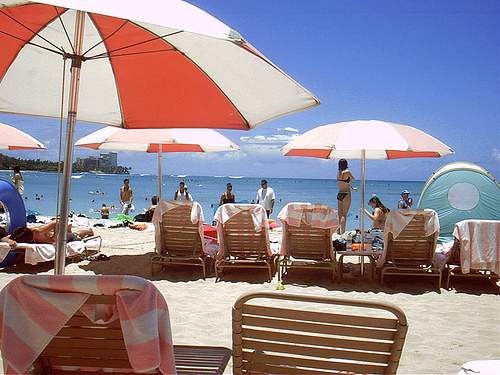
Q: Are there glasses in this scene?
A: No, there are no glasses.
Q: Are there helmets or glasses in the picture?
A: No, there are no glasses or helmets.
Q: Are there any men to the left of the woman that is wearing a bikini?
A: Yes, there is a man to the left of the woman.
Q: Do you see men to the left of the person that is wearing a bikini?
A: Yes, there is a man to the left of the woman.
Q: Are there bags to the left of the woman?
A: No, there is a man to the left of the woman.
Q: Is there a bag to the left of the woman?
A: No, there is a man to the left of the woman.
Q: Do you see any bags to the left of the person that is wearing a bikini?
A: No, there is a man to the left of the woman.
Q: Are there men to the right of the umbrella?
A: No, the man is to the left of the umbrella.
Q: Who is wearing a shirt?
A: The man is wearing a shirt.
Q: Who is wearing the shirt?
A: The man is wearing a shirt.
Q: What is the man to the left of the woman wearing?
A: The man is wearing a shirt.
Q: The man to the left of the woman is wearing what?
A: The man is wearing a shirt.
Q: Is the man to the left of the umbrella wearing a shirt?
A: Yes, the man is wearing a shirt.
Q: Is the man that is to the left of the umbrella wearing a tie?
A: No, the man is wearing a shirt.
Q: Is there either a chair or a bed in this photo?
A: Yes, there is a chair.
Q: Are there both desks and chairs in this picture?
A: No, there is a chair but no desks.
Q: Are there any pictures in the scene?
A: No, there are no pictures.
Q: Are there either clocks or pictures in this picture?
A: No, there are no pictures or clocks.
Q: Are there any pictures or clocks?
A: No, there are no pictures or clocks.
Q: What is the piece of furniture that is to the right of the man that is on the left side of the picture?
A: The piece of furniture is a chair.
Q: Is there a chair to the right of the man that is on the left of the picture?
A: Yes, there is a chair to the right of the man.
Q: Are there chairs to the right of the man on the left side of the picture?
A: Yes, there is a chair to the right of the man.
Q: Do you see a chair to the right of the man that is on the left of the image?
A: Yes, there is a chair to the right of the man.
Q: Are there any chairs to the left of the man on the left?
A: No, the chair is to the right of the man.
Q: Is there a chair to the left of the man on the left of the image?
A: No, the chair is to the right of the man.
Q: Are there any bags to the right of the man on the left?
A: No, there is a chair to the right of the man.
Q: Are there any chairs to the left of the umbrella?
A: Yes, there is a chair to the left of the umbrella.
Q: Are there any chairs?
A: Yes, there is a chair.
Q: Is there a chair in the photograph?
A: Yes, there is a chair.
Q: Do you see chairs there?
A: Yes, there is a chair.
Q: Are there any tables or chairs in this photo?
A: Yes, there is a chair.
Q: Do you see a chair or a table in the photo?
A: Yes, there is a chair.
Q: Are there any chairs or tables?
A: Yes, there is a chair.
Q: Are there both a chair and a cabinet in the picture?
A: No, there is a chair but no cabinets.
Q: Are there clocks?
A: No, there are no clocks.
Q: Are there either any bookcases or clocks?
A: No, there are no clocks or bookcases.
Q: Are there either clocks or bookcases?
A: No, there are no clocks or bookcases.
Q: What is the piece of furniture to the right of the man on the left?
A: The piece of furniture is a chair.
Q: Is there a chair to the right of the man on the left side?
A: Yes, there is a chair to the right of the man.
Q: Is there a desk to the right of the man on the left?
A: No, there is a chair to the right of the man.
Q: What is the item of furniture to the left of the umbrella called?
A: The piece of furniture is a chair.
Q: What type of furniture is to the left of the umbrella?
A: The piece of furniture is a chair.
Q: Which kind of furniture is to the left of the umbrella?
A: The piece of furniture is a chair.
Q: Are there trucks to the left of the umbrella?
A: No, there is a chair to the left of the umbrella.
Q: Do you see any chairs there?
A: Yes, there is a chair.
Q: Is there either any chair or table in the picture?
A: Yes, there is a chair.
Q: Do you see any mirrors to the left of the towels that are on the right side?
A: No, there is a chair to the left of the towels.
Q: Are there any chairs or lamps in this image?
A: Yes, there is a chair.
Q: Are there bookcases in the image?
A: No, there are no bookcases.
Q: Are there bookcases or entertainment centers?
A: No, there are no bookcases or entertainment centers.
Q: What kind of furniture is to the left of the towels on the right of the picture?
A: The piece of furniture is a chair.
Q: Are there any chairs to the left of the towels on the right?
A: Yes, there is a chair to the left of the towels.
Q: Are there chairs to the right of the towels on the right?
A: No, the chair is to the left of the towels.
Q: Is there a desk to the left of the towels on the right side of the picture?
A: No, there is a chair to the left of the towels.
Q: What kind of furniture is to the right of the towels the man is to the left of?
A: The piece of furniture is a chair.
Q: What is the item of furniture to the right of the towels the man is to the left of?
A: The piece of furniture is a chair.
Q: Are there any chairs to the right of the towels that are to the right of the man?
A: Yes, there is a chair to the right of the towels.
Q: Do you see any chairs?
A: Yes, there is a chair.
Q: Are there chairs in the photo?
A: Yes, there is a chair.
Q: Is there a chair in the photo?
A: Yes, there is a chair.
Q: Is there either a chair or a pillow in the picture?
A: Yes, there is a chair.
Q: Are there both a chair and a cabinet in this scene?
A: No, there is a chair but no cabinets.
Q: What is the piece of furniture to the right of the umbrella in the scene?
A: The piece of furniture is a chair.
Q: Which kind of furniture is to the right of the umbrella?
A: The piece of furniture is a chair.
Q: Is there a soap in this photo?
A: No, there are no soaps.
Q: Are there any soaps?
A: No, there are no soaps.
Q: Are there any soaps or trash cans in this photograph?
A: No, there are no soaps or trash cans.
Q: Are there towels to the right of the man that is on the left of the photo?
A: Yes, there are towels to the right of the man.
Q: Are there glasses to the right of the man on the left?
A: No, there are towels to the right of the man.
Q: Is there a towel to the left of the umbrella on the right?
A: Yes, there are towels to the left of the umbrella.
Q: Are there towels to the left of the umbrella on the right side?
A: Yes, there are towels to the left of the umbrella.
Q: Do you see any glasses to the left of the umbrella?
A: No, there are towels to the left of the umbrella.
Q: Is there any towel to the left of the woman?
A: Yes, there are towels to the left of the woman.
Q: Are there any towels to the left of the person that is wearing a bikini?
A: Yes, there are towels to the left of the woman.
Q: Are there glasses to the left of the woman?
A: No, there are towels to the left of the woman.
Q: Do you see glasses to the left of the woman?
A: No, there are towels to the left of the woman.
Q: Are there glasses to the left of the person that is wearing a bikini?
A: No, there are towels to the left of the woman.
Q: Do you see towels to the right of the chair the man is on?
A: Yes, there are towels to the right of the chair.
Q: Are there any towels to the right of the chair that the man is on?
A: Yes, there are towels to the right of the chair.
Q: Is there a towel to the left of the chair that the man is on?
A: No, the towels are to the right of the chair.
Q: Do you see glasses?
A: No, there are no glasses.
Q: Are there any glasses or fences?
A: No, there are no glasses or fences.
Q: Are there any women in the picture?
A: Yes, there is a woman.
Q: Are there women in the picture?
A: Yes, there is a woman.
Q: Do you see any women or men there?
A: Yes, there is a woman.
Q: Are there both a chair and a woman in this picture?
A: Yes, there are both a woman and a chair.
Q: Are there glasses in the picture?
A: No, there are no glasses.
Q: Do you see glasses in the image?
A: No, there are no glasses.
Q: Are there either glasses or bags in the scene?
A: No, there are no glasses or bags.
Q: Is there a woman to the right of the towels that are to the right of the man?
A: Yes, there is a woman to the right of the towels.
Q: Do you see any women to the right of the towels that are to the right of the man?
A: Yes, there is a woman to the right of the towels.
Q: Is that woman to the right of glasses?
A: No, the woman is to the right of the towels.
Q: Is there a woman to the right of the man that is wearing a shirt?
A: Yes, there is a woman to the right of the man.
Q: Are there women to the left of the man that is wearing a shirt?
A: No, the woman is to the right of the man.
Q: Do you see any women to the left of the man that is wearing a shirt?
A: No, the woman is to the right of the man.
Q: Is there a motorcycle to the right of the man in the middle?
A: No, there is a woman to the right of the man.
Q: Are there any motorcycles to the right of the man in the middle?
A: No, there is a woman to the right of the man.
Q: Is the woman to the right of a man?
A: Yes, the woman is to the right of a man.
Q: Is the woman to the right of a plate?
A: No, the woman is to the right of a man.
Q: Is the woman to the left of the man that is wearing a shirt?
A: No, the woman is to the right of the man.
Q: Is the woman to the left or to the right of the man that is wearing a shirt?
A: The woman is to the right of the man.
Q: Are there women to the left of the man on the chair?
A: Yes, there is a woman to the left of the man.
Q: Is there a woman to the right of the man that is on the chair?
A: No, the woman is to the left of the man.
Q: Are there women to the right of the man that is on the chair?
A: No, the woman is to the left of the man.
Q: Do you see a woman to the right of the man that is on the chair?
A: No, the woman is to the left of the man.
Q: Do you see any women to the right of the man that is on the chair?
A: No, the woman is to the left of the man.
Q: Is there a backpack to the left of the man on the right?
A: No, there is a woman to the left of the man.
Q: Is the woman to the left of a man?
A: Yes, the woman is to the left of a man.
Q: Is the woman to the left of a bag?
A: No, the woman is to the left of a man.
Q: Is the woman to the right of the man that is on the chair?
A: No, the woman is to the left of the man.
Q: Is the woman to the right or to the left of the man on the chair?
A: The woman is to the left of the man.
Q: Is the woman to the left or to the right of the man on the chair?
A: The woman is to the left of the man.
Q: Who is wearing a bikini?
A: The woman is wearing a bikini.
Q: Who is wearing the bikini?
A: The woman is wearing a bikini.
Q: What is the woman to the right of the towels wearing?
A: The woman is wearing a bikini.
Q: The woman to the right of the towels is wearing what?
A: The woman is wearing a bikini.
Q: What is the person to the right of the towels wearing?
A: The woman is wearing a bikini.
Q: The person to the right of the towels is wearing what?
A: The woman is wearing a bikini.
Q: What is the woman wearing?
A: The woman is wearing a bikini.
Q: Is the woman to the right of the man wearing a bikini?
A: Yes, the woman is wearing a bikini.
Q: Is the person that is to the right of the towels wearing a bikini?
A: Yes, the woman is wearing a bikini.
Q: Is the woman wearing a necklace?
A: No, the woman is wearing a bikini.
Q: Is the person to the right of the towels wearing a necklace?
A: No, the woman is wearing a bikini.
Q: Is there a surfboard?
A: No, there are no surfboards.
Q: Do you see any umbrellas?
A: Yes, there is an umbrella.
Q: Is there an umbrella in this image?
A: Yes, there is an umbrella.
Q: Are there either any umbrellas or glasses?
A: Yes, there is an umbrella.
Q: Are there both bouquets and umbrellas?
A: No, there is an umbrella but no bouquets.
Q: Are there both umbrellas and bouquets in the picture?
A: No, there is an umbrella but no bouquets.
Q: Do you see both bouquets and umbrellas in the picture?
A: No, there is an umbrella but no bouquets.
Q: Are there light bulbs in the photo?
A: No, there are no light bulbs.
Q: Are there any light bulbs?
A: No, there are no light bulbs.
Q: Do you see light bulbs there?
A: No, there are no light bulbs.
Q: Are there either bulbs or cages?
A: No, there are no bulbs or cages.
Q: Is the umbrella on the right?
A: Yes, the umbrella is on the right of the image.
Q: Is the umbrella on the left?
A: No, the umbrella is on the right of the image.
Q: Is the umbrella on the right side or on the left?
A: The umbrella is on the right of the image.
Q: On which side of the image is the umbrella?
A: The umbrella is on the right of the image.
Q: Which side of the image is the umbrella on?
A: The umbrella is on the right of the image.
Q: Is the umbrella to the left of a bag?
A: No, the umbrella is to the left of a chair.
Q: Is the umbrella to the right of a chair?
A: Yes, the umbrella is to the right of a chair.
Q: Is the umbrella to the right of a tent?
A: No, the umbrella is to the right of a chair.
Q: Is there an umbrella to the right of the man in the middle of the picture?
A: Yes, there is an umbrella to the right of the man.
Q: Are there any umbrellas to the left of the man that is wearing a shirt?
A: No, the umbrella is to the right of the man.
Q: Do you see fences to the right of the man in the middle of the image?
A: No, there is an umbrella to the right of the man.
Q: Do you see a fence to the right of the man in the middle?
A: No, there is an umbrella to the right of the man.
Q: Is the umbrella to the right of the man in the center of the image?
A: Yes, the umbrella is to the right of the man.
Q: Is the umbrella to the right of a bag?
A: No, the umbrella is to the right of the man.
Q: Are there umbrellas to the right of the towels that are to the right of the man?
A: Yes, there is an umbrella to the right of the towels.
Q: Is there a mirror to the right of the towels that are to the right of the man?
A: No, there is an umbrella to the right of the towels.